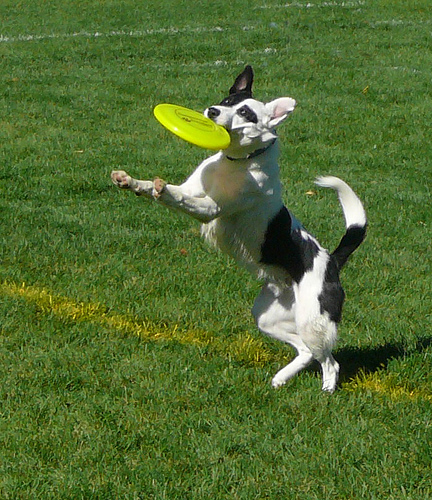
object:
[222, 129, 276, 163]
black collar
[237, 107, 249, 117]
dog's eye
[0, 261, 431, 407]
stripe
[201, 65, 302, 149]
head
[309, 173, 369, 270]
tail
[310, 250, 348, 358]
haunches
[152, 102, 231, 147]
frisbee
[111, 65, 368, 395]
dog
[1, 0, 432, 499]
grass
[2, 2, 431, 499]
field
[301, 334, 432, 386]
shadow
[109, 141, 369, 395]
body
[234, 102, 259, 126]
patch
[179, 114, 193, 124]
logo